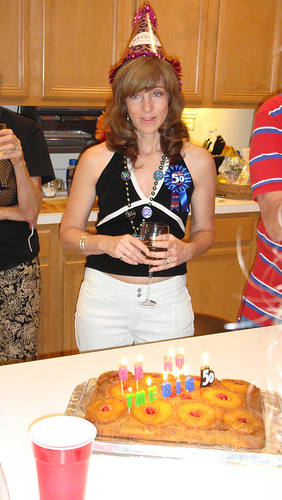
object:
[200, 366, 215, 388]
50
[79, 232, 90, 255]
bracelet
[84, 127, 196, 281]
shirt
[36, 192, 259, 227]
countertop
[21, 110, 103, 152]
toaster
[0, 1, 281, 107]
cabinet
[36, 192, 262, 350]
cabinet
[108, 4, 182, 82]
birthday hat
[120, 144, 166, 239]
beads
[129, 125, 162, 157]
neck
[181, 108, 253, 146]
ground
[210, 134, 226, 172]
knife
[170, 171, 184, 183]
50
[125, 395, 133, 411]
candle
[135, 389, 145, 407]
candle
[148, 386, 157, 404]
candle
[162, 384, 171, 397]
candle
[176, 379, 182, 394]
candle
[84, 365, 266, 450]
birthday cake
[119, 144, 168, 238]
necklace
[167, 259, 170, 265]
ring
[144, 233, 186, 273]
left hand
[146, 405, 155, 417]
cherry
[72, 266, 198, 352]
pants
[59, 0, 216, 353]
girl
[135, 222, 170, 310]
glass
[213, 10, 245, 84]
brown cabinets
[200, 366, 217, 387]
candle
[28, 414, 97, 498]
cup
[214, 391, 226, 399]
cherry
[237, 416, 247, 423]
cherry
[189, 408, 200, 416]
cherry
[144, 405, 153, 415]
cherry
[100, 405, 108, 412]
cherry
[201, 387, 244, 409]
slice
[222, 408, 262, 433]
slice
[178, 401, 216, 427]
slice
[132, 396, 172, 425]
slice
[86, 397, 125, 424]
slice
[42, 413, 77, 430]
inside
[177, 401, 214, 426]
pineapple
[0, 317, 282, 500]
table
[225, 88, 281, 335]
person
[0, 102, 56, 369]
person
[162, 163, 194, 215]
ribbon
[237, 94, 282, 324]
shirt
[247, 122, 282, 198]
stripes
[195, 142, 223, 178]
holder